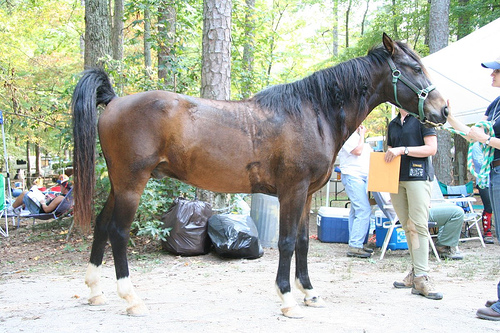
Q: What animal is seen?
A: Horse.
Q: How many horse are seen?
A: One.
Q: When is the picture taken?
A: Daytime.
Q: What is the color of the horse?
A: Brown and black.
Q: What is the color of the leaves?
A: Green.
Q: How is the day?
A: Sunny.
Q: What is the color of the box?
A: Blue.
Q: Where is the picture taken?
A: At a campsite.